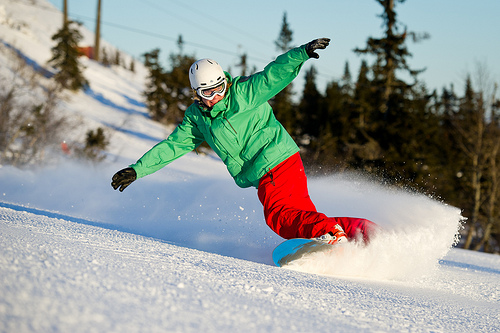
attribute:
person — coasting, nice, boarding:
[109, 33, 385, 257]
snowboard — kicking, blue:
[270, 236, 370, 266]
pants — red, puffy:
[256, 155, 379, 244]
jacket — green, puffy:
[131, 44, 307, 193]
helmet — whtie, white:
[185, 56, 226, 87]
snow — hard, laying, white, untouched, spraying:
[345, 218, 464, 285]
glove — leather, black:
[111, 165, 138, 191]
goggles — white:
[199, 76, 233, 102]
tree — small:
[341, 12, 407, 174]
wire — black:
[28, 5, 277, 65]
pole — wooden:
[91, 0, 103, 63]